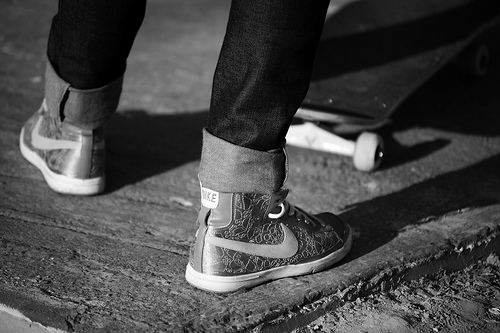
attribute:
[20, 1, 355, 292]
person — young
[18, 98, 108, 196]
shoe — nike, hightop, patterned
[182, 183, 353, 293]
shoe — nike, hightop, patterned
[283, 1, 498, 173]
skateboard — dark, black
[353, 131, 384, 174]
wheel — white, light, rear right, light colored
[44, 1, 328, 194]
pants — black, denim, straight legged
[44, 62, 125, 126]
cuff — rolled up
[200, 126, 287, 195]
cuff — rolled up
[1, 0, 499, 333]
ground — dirty, wooden, cement, cracked, concrete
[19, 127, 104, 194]
sole — white, light colored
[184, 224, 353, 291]
sole — white, light colored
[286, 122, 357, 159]
axle — light, silver, metal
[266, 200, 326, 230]
laces — white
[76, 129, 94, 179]
stripe — dark colored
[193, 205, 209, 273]
stripe — dark colored